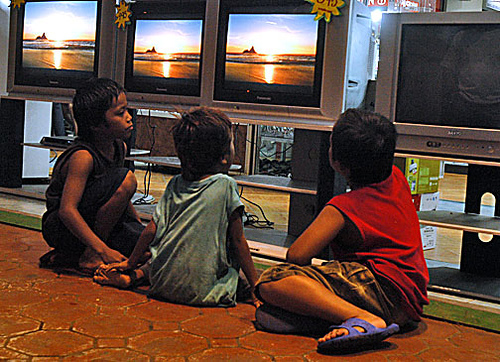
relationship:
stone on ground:
[2, 200, 497, 357] [2, 220, 484, 352]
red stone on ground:
[71, 310, 151, 336] [1, 277, 261, 359]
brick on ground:
[129, 329, 209, 354] [2, 220, 484, 352]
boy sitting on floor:
[252, 107, 427, 352] [17, 266, 145, 354]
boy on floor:
[37, 78, 136, 273] [30, 325, 463, 360]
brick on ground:
[78, 346, 151, 358] [2, 220, 484, 352]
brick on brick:
[183, 346, 272, 360] [78, 346, 151, 358]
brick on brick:
[177, 311, 254, 336] [78, 346, 151, 358]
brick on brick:
[447, 328, 499, 352] [78, 346, 151, 358]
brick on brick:
[23, 292, 100, 319] [78, 346, 151, 358]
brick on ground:
[71, 311, 154, 339] [2, 220, 484, 352]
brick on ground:
[71, 314, 151, 336] [12, 295, 253, 355]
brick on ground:
[123, 322, 216, 356] [2, 220, 484, 352]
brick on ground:
[239, 329, 317, 355] [2, 220, 484, 352]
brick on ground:
[301, 346, 399, 361] [2, 220, 484, 352]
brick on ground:
[7, 240, 30, 249] [2, 220, 484, 352]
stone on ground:
[451, 319, 497, 359] [2, 220, 484, 352]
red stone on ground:
[69, 301, 150, 356] [12, 317, 238, 352]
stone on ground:
[415, 310, 461, 342] [2, 220, 484, 352]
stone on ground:
[368, 343, 413, 359] [125, 298, 195, 331]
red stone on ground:
[196, 328, 252, 360] [3, 210, 498, 359]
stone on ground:
[121, 321, 222, 361] [100, 305, 200, 350]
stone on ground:
[24, 301, 121, 351] [1, 315, 215, 360]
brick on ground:
[158, 310, 225, 342] [424, 330, 498, 357]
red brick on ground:
[128, 327, 211, 357] [5, 272, 209, 359]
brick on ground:
[24, 290, 105, 326] [2, 220, 484, 352]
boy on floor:
[252, 107, 427, 352] [8, 250, 482, 357]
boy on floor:
[100, 103, 257, 303] [8, 250, 482, 357]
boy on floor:
[39, 76, 136, 271] [8, 250, 482, 357]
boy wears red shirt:
[252, 107, 427, 352] [326, 165, 430, 318]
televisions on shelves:
[4, 2, 498, 159] [10, 4, 499, 302]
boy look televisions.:
[94, 104, 258, 309] [47, 7, 389, 109]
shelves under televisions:
[1, 94, 498, 307] [4, 2, 498, 159]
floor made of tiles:
[1, 222, 498, 359] [6, 329, 96, 360]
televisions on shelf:
[197, 0, 373, 131] [219, 117, 330, 262]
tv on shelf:
[119, 0, 210, 101] [8, 100, 477, 297]